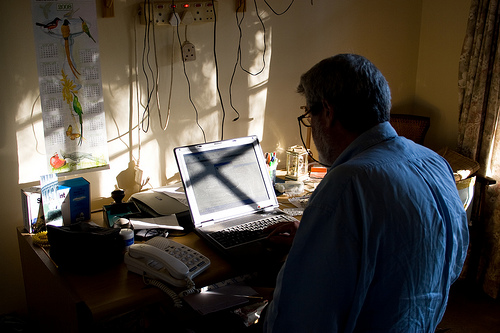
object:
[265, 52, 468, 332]
man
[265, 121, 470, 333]
collared shirt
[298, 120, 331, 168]
strap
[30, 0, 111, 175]
poster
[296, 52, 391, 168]
head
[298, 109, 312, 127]
eyeglasses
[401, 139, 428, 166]
ground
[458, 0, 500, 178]
curtains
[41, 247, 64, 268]
pencil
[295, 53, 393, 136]
hair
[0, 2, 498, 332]
room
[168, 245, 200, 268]
big button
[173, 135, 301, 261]
laptop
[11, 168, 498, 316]
desk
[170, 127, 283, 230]
woman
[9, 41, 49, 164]
all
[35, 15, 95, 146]
birds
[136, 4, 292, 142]
cables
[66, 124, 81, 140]
butterfly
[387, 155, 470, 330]
wrinkles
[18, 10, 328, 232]
sunshine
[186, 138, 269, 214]
shadow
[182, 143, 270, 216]
screen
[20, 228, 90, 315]
corner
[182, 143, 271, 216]
light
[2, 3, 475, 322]
wall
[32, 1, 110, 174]
calendar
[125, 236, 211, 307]
telephone